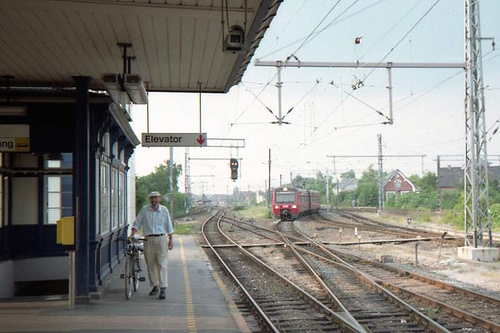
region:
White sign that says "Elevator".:
[141, 132, 206, 145]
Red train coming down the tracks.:
[273, 185, 320, 219]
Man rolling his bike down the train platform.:
[129, 191, 172, 298]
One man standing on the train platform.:
[130, 190, 173, 298]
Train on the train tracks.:
[272, 185, 321, 221]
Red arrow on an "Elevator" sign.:
[196, 133, 206, 144]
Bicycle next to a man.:
[113, 236, 147, 299]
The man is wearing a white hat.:
[150, 190, 160, 196]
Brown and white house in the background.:
[381, 168, 413, 205]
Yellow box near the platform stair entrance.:
[56, 215, 74, 244]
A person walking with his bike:
[113, 188, 177, 303]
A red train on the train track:
[267, 183, 337, 223]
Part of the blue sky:
[428, 29, 438, 54]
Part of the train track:
[240, 253, 258, 300]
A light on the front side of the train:
[278, 183, 290, 193]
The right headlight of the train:
[273, 201, 282, 209]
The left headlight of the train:
[288, 202, 298, 211]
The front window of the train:
[273, 190, 298, 204]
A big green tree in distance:
[353, 160, 383, 208]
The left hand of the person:
[166, 236, 176, 251]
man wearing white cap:
[98, 178, 197, 303]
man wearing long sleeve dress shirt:
[128, 182, 180, 300]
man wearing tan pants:
[105, 185, 175, 297]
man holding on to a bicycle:
[110, 177, 203, 297]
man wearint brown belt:
[97, 163, 193, 303]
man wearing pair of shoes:
[110, 177, 185, 304]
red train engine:
[235, 170, 345, 261]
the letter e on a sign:
[123, 118, 233, 158]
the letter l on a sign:
[128, 120, 249, 168]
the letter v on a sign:
[133, 125, 222, 163]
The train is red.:
[258, 182, 322, 217]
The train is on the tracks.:
[243, 174, 322, 216]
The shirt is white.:
[125, 199, 183, 236]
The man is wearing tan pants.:
[132, 236, 171, 280]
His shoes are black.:
[140, 277, 177, 302]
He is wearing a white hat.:
[147, 184, 164, 196]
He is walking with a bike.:
[115, 177, 190, 297]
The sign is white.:
[140, 121, 214, 151]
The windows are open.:
[4, 146, 130, 229]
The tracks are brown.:
[190, 199, 450, 330]